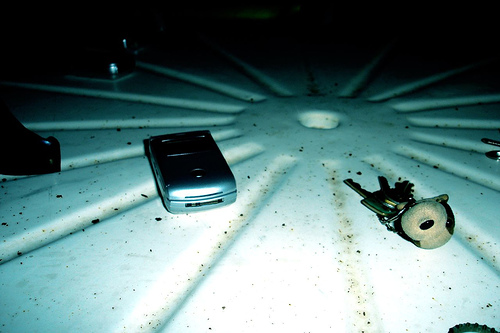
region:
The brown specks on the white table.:
[26, 96, 497, 328]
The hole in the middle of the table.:
[297, 105, 350, 139]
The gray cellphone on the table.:
[139, 130, 233, 210]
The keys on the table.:
[344, 168, 411, 218]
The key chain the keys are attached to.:
[389, 198, 457, 250]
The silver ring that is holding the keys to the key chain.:
[384, 208, 416, 220]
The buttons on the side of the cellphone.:
[147, 158, 162, 182]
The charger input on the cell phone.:
[182, 200, 224, 206]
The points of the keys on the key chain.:
[341, 168, 409, 192]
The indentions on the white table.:
[21, 52, 488, 317]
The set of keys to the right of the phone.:
[347, 165, 423, 215]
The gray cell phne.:
[158, 130, 240, 217]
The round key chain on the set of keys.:
[405, 198, 452, 249]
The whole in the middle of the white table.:
[293, 108, 345, 135]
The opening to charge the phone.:
[182, 198, 228, 208]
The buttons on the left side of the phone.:
[147, 155, 161, 179]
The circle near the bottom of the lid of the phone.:
[184, 169, 208, 183]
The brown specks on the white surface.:
[51, 70, 457, 331]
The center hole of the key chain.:
[417, 216, 435, 231]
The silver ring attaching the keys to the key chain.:
[380, 203, 413, 229]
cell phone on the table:
[129, 119, 256, 228]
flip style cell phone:
[136, 126, 258, 219]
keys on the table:
[334, 158, 461, 271]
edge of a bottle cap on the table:
[421, 302, 488, 330]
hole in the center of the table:
[284, 102, 344, 150]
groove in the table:
[16, 206, 98, 254]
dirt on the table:
[325, 168, 354, 244]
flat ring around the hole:
[216, 90, 428, 165]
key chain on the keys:
[402, 202, 459, 257]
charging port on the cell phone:
[181, 192, 233, 210]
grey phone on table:
[149, 104, 250, 215]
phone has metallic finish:
[161, 141, 251, 216]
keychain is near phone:
[349, 166, 451, 243]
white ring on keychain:
[396, 199, 451, 243]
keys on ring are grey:
[354, 164, 420, 232]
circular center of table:
[244, 94, 353, 158]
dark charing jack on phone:
[178, 191, 242, 216]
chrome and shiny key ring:
[371, 193, 411, 228]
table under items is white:
[88, 29, 473, 306]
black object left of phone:
[0, 104, 66, 191]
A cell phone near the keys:
[143, 132, 231, 210]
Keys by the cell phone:
[348, 176, 448, 248]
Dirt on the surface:
[5, 85, 492, 331]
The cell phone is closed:
[145, 131, 227, 212]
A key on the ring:
[345, 170, 393, 214]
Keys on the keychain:
[348, 172, 413, 212]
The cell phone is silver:
[142, 133, 236, 211]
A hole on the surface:
[301, 110, 338, 132]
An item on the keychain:
[398, 197, 454, 245]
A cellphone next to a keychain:
[141, 128, 458, 247]